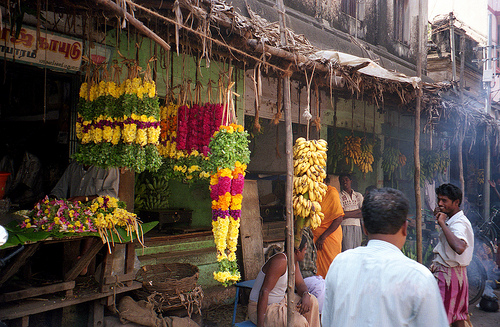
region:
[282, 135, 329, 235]
a bunch of bananas hanging from the building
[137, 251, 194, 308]
a basket on the outside of the building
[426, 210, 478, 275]
a white shirt on a man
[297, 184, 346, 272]
a orange dress on the woman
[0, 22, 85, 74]
a white and red sign on the building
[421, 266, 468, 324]
a colorful piece of fabric on a man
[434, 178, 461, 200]
the black hair of a man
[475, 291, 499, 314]
a small black pot on the ground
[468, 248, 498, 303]
smoke coming from a pot on the ground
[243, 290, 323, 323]
a pair of beige pants on a man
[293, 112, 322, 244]
Bunch of yellow bananas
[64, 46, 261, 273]
Flower garlands hanging from the roof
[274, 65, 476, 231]
Fruit shop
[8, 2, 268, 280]
Flower shop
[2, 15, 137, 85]
A sign in foreign language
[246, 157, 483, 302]
Male fruit and flower vendors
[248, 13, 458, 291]
Supports for roof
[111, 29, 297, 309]
Green wall behind the flower garlands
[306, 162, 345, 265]
A woman wearing yellow spree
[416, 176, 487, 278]
A man in white shirt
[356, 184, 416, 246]
Back of man's head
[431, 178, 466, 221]
Smiling man raising his arms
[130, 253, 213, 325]
Woven food holding basket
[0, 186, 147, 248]
Flowers laying on a shelf for sale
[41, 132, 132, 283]
Man sitting behind the counter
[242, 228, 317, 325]
Man sitting down, engaged in conversation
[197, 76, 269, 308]
Hanging decorative flowers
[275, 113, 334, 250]
Bushel of hanging bananas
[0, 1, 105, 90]
Sign for the marketplace shop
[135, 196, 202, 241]
Small black chest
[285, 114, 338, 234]
Group of bananas hanging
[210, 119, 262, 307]
Vegetable hanging on a string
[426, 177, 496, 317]
Man talking to other people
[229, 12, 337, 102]
Wood roofing on building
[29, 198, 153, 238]
Food on top of the counter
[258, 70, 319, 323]
Wooden pole holding up the roof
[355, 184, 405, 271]
Man with dark hair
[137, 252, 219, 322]
Basket sitting in corner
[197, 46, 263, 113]
Rope twine holding up food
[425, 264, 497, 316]
Man wearing shirt tied around waist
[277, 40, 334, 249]
a handle of bananas hang from a roof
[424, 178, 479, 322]
man wearing a white shirt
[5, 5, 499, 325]
a market on the street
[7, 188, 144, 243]
bouquet of flowers on display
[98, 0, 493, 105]
awning of a roof is old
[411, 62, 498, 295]
smoke coming behind a man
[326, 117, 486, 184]
handles of bananas hanging from roof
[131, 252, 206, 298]
an empty basket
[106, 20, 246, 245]
a green wall of a store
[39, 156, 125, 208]
shirt with a pocket